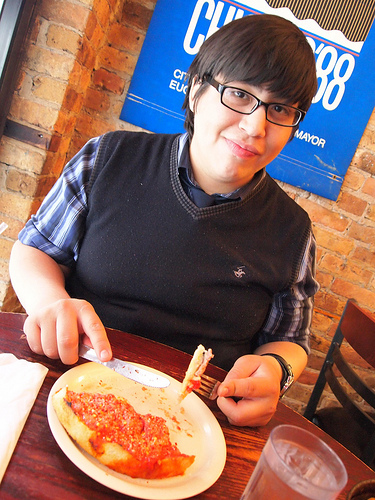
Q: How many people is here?
A: One.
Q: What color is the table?
A: Brown.